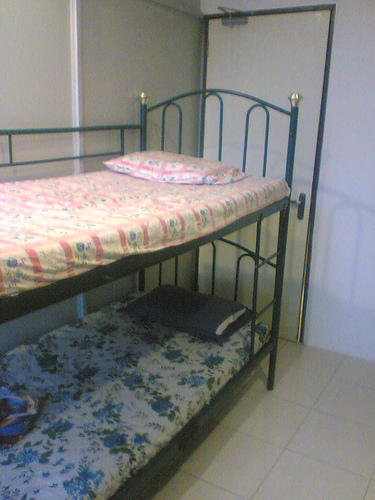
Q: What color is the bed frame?
A: Green.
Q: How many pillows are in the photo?
A: Two.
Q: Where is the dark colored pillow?
A: On the bottom bunk.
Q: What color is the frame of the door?
A: Green.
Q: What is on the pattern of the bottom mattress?
A: Flowers.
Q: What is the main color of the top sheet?
A: Pink.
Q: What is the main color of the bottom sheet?
A: Blue.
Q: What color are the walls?
A: White.